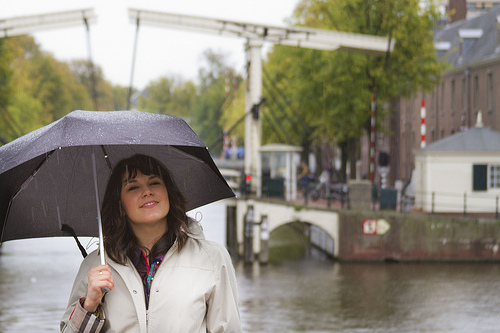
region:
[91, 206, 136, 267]
A woman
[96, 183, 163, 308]
A woman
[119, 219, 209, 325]
A woman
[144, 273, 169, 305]
A woman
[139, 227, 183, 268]
A woman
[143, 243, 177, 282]
A woman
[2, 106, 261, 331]
Lady holding black umbrella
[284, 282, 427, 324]
Water in a canal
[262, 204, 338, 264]
White bridge over canal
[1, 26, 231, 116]
Trees behind the canal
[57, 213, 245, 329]
Beige rain jacket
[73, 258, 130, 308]
Hand holding an umbrella handle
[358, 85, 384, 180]
Red and white crossing gates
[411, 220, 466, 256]
Mossy brick wall around canal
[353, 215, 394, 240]
Sign on brick wall around canal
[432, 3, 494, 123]
Two story red brick building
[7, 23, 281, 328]
A woman holding an umbrella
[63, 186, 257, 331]
A white rain jacket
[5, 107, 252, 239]
A black umbrella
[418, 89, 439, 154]
A red and white striped pole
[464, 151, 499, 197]
Green shudders near a window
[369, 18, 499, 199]
A large brick building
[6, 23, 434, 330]
Trees near a river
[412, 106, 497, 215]
A white building near the river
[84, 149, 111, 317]
A chrome umbrella handle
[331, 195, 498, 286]
A cement breakwall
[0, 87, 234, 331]
woman holding an umbrella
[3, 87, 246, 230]
the umbrella is black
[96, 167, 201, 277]
the woman is smiling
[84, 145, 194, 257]
woman's hair is brown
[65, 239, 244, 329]
woman's jacket is light brown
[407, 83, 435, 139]
the pole is striped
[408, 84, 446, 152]
the pole is red and white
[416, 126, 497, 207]
the building is white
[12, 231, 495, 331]
body of water behind woman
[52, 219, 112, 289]
black strap to umbrella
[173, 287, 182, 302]
the coat is brown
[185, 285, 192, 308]
the coat is brown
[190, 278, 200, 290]
the coat is brown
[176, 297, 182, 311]
the coat is brown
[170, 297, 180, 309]
the coat is brown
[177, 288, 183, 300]
the coat is brown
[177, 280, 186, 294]
the coat is brown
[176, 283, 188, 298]
the coat is brown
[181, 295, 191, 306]
the coat is brown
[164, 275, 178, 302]
the coat is brown